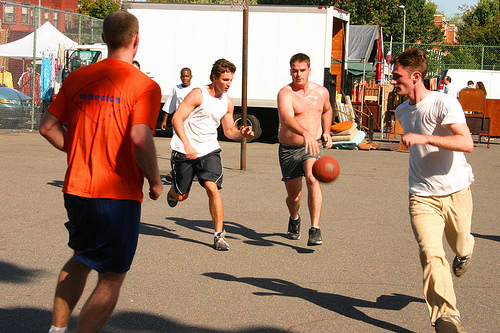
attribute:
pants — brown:
[404, 170, 486, 332]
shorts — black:
[160, 148, 255, 225]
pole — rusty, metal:
[235, 3, 255, 172]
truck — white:
[132, 1, 344, 124]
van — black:
[54, 3, 365, 158]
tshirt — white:
[380, 95, 486, 200]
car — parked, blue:
[0, 80, 35, 129]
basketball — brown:
[310, 155, 341, 185]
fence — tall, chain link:
[5, 5, 101, 104]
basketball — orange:
[311, 157, 339, 183]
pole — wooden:
[231, 17, 267, 192]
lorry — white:
[147, 17, 347, 98]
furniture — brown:
[457, 89, 498, 145]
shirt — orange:
[57, 65, 177, 222]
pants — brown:
[405, 187, 477, 331]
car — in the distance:
[0, 69, 47, 134]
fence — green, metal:
[388, 22, 499, 74]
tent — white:
[1, 19, 87, 86]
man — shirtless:
[276, 52, 335, 245]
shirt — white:
[170, 82, 199, 127]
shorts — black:
[168, 152, 220, 192]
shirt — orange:
[45, 57, 158, 201]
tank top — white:
[175, 85, 225, 157]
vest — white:
[174, 84, 228, 154]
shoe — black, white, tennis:
[305, 225, 322, 253]